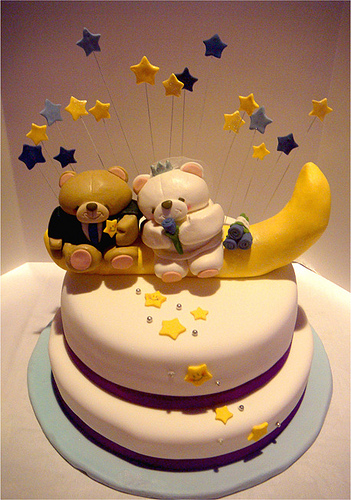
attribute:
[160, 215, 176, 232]
rose — blue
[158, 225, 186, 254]
holder — green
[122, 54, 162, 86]
star — yellow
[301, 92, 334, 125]
star — yellow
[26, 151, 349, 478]
cake — yellow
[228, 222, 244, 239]
flower — blue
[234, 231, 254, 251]
flower — blue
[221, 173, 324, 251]
flower — blue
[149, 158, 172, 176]
crown — grey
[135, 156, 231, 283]
bear — white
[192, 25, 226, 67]
star — bottom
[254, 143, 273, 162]
star — yellow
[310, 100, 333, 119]
star — blue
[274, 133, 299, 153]
star — blue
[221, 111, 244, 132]
star — yellow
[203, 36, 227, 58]
star — yellow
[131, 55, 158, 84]
star — yellow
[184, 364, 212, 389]
star — yellow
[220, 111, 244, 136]
star — yellow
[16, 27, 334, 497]
cake — two layer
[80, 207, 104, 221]
nose — Brown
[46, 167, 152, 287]
bear — Brown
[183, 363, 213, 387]
face — smiley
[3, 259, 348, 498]
tablecloth — white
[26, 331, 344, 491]
plate — Light, blue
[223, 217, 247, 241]
towel — blue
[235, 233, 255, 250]
towel — blue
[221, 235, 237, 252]
towel — blue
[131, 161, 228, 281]
teddy bear — white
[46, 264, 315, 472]
cake — two layer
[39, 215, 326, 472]
cake — white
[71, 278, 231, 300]
shadow — teddy bears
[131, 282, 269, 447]
star — yellow confectionary 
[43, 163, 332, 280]
moon — confectionary